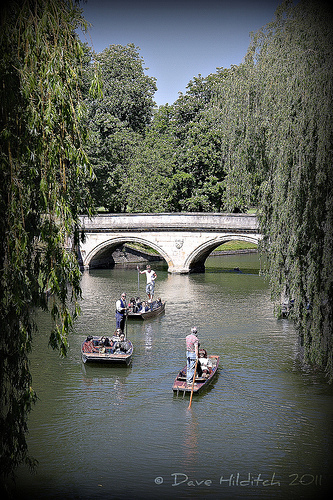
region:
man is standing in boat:
[77, 290, 134, 366]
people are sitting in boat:
[82, 329, 132, 362]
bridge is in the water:
[15, 204, 315, 274]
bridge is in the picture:
[30, 212, 319, 278]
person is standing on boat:
[172, 325, 220, 413]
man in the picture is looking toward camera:
[113, 288, 132, 342]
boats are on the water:
[37, 256, 286, 456]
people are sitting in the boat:
[129, 288, 168, 316]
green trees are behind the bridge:
[54, 44, 316, 279]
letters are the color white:
[154, 470, 331, 498]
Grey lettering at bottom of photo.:
[135, 458, 283, 497]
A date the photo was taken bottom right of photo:
[281, 461, 330, 491]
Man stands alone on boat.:
[183, 323, 202, 387]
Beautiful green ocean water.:
[75, 414, 173, 458]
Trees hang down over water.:
[4, 286, 76, 408]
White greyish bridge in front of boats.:
[79, 217, 261, 226]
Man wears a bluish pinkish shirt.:
[185, 330, 198, 353]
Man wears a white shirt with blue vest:
[112, 299, 129, 311]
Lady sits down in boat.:
[83, 331, 98, 364]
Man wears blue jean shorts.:
[142, 284, 158, 295]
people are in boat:
[77, 290, 134, 368]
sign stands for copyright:
[153, 469, 168, 493]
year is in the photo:
[288, 470, 332, 490]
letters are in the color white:
[152, 469, 325, 496]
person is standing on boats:
[169, 326, 220, 407]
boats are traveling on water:
[61, 254, 289, 441]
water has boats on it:
[45, 289, 276, 408]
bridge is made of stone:
[15, 203, 302, 275]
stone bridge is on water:
[26, 205, 319, 285]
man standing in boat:
[180, 325, 198, 383]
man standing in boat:
[139, 258, 157, 302]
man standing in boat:
[110, 293, 133, 333]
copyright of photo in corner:
[145, 468, 318, 490]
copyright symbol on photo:
[149, 472, 167, 489]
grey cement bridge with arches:
[84, 210, 264, 278]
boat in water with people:
[174, 324, 223, 410]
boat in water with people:
[73, 329, 133, 376]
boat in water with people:
[127, 281, 175, 320]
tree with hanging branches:
[236, 77, 324, 320]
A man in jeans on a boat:
[177, 320, 205, 385]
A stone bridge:
[69, 207, 281, 270]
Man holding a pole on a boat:
[134, 263, 160, 315]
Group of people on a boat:
[78, 327, 135, 365]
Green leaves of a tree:
[12, 10, 96, 471]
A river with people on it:
[66, 252, 291, 467]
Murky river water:
[47, 402, 311, 480]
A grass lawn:
[220, 240, 252, 248]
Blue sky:
[72, 0, 244, 59]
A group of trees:
[68, 67, 246, 191]